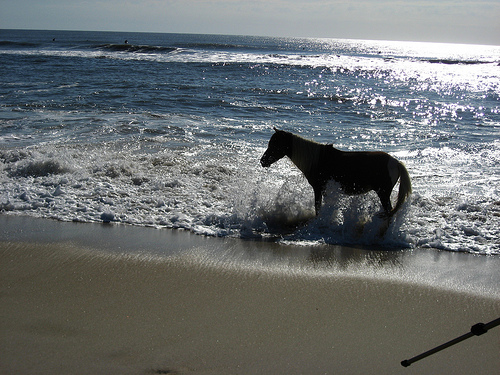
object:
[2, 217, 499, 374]
sand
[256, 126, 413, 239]
horse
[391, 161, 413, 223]
tail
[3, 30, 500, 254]
ocean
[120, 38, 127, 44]
bird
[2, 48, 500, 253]
wave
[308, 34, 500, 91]
reflection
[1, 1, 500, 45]
sky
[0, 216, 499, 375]
beach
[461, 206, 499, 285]
object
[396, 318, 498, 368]
shadow